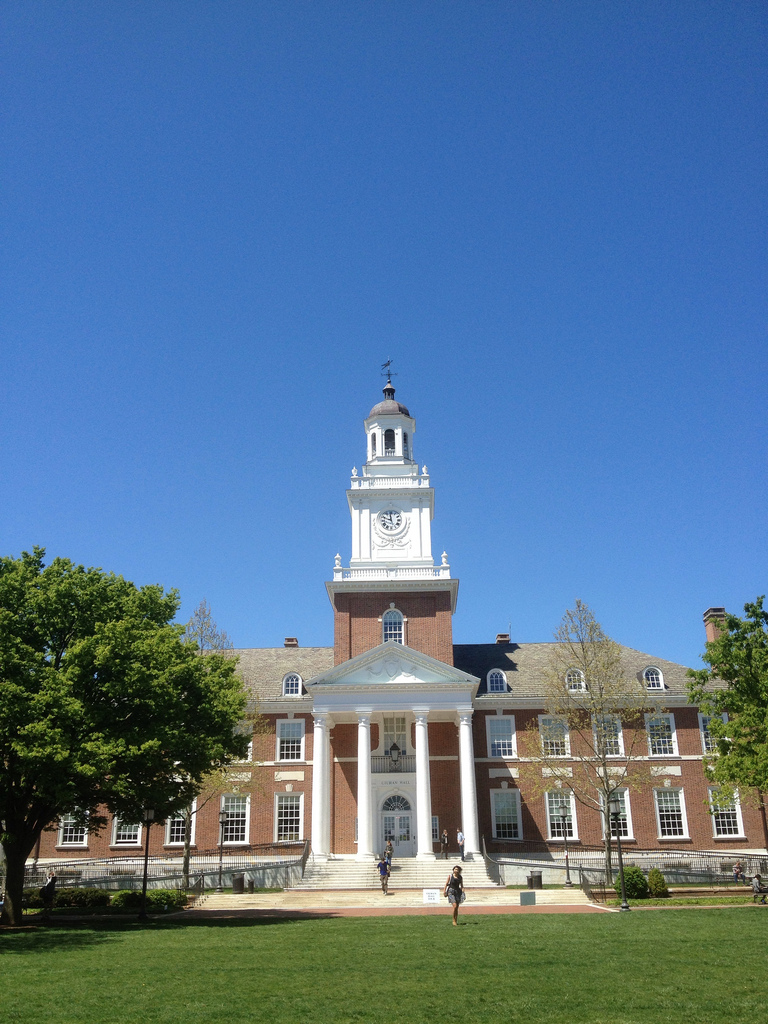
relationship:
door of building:
[361, 777, 419, 871] [76, 631, 762, 871]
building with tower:
[21, 350, 756, 900] [356, 337, 439, 512]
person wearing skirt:
[444, 866, 466, 926] [446, 884, 463, 903]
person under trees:
[443, 852, 474, 928] [0, 534, 251, 922]